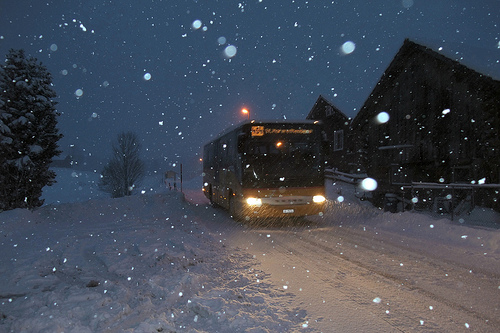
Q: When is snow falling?
A: At night.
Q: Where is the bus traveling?
A: In the snow.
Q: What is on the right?
A: Dark building.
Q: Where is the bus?
A: In the snow.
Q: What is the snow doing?
A: Falling.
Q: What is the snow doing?
A: Falling.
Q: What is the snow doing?
A: Falling.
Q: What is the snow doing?
A: Falling.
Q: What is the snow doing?
A: Falling.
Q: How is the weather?
A: Snowing.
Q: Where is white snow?
A: On the ground.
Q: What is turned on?
A: Bus headlights.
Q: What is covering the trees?
A: Snow.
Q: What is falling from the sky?
A: Snow.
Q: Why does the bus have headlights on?
A: It is getting dark.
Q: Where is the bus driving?
A: On a snowy road.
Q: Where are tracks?
A: On the road.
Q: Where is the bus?
A: Road.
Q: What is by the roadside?
A: House.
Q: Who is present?
A: No one.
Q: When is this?
A: Night time.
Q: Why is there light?
A: Vision.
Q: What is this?
A: Bus.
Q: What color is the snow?
A: White.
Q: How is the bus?
A: In motion.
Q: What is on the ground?
A: Snow.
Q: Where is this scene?
A: A snowstorm.